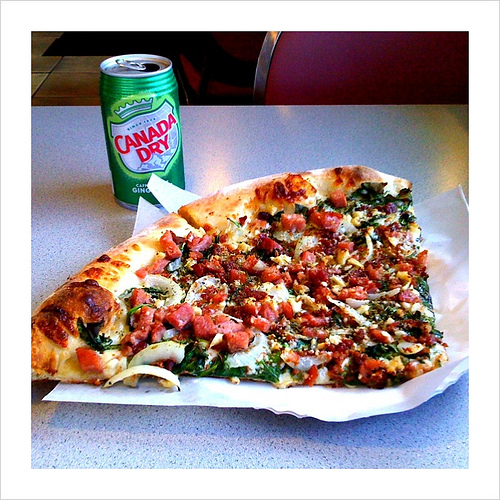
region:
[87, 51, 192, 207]
can sitting on table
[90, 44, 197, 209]
can on table is green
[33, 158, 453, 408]
slice of pizza on paper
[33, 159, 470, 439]
pizza on paper sitting on table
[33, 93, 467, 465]
table is holding food and drink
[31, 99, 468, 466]
table is white and black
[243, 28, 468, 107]
chair next to table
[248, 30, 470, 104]
chair at table is red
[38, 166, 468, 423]
paper is holding slice of pizza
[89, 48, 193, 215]
green can reads ginger ale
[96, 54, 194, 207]
A CAN of Canada Dry.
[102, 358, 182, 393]
An onion on a napkin.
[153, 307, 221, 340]
Several pieces of Canadian Bacon.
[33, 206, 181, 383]
Thick pizza crust.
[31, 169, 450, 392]
Two large slices of pizza.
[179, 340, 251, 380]
Several piecs of Oregano.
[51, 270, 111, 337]
A burnt, raised section of crust.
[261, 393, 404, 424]
A piece of white napkin.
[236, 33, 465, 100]
A red chair with a silver frame.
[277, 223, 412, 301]
A multi colored assortment of toppings.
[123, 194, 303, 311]
two slices of pizza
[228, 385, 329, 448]
pizza is on a plate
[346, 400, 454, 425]
paper is under the pizza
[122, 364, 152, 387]
onion on the pizza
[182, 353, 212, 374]
spinach on the pizza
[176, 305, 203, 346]
canadian bacon on the pizza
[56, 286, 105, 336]
burnt on the crust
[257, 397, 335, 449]
plate is on the table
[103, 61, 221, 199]
green can next to pizza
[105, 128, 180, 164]
CANADA DRY written on the can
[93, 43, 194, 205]
a can of Canada Dry ginger ale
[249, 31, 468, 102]
a red chair at a table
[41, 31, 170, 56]
a rug on a tile floor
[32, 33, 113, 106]
a tile floor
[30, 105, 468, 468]
a white table with speckles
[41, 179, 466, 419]
a white paper under a pizza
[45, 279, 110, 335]
a dark bubble on a pizza crust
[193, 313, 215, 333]
a tomato piece on a pizza slice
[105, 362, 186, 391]
a piece of white onion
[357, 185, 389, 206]
spinach on a pizza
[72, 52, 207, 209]
Green tin can drink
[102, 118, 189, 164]
Red letters on a tin can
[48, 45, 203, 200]
Green tin can sitting on a table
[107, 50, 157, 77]
Metal tab to a can soda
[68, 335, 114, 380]
Red tomato on a pizza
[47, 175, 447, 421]
Two slices of a pizza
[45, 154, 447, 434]
Slizes of pizza on a plate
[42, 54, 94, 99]
Dark brown tiled floors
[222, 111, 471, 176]
Reflection of light on table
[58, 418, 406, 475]
Dark speckled table